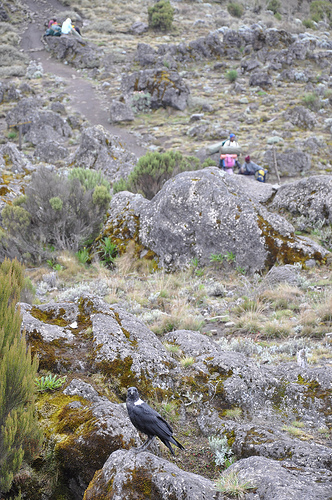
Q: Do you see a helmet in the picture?
A: No, there are no helmets.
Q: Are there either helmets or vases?
A: No, there are no helmets or vases.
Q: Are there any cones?
A: No, there are no cones.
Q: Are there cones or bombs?
A: No, there are no cones or bombs.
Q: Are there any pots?
A: No, there are no pots.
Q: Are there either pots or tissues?
A: No, there are no pots or tissues.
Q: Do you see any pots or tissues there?
A: No, there are no pots or tissues.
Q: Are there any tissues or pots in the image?
A: No, there are no pots or tissues.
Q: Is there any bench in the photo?
A: No, there are no benches.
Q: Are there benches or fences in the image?
A: No, there are no benches or fences.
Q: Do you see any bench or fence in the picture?
A: No, there are no benches or fences.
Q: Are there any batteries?
A: No, there are no batteries.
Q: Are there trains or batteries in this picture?
A: No, there are no batteries or trains.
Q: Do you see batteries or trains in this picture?
A: No, there are no batteries or trains.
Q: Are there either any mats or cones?
A: No, there are no cones or mats.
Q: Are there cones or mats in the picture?
A: No, there are no cones or mats.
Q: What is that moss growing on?
A: The moss is growing on the rocks.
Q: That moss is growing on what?
A: The moss is growing on the rocks.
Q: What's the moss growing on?
A: The moss is growing on the rocks.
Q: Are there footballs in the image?
A: No, there are no footballs.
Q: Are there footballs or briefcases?
A: No, there are no footballs or briefcases.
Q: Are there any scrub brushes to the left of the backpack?
A: Yes, there is a scrub brush to the left of the backpack.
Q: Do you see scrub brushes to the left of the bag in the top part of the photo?
A: Yes, there is a scrub brush to the left of the backpack.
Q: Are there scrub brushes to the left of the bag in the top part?
A: Yes, there is a scrub brush to the left of the backpack.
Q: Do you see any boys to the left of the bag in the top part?
A: No, there is a scrub brush to the left of the backpack.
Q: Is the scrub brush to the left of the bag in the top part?
A: Yes, the scrub brush is to the left of the backpack.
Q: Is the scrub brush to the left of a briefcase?
A: No, the scrub brush is to the left of the backpack.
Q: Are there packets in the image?
A: No, there are no packets.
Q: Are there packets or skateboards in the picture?
A: No, there are no packets or skateboards.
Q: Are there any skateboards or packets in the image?
A: No, there are no packets or skateboards.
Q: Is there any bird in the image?
A: Yes, there is a bird.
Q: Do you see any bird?
A: Yes, there is a bird.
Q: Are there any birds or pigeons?
A: Yes, there is a bird.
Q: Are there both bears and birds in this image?
A: No, there is a bird but no bears.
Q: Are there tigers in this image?
A: No, there are no tigers.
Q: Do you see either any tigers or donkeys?
A: No, there are no tigers or donkeys.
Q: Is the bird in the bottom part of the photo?
A: Yes, the bird is in the bottom of the image.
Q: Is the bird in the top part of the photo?
A: No, the bird is in the bottom of the image.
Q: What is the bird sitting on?
A: The bird is sitting on the rock.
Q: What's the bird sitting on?
A: The bird is sitting on the rock.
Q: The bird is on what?
A: The bird is on the rock.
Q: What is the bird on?
A: The bird is on the rock.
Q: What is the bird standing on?
A: The bird is standing on the rock.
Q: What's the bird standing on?
A: The bird is standing on the rock.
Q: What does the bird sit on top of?
A: The bird sits on top of the rock.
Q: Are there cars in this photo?
A: No, there are no cars.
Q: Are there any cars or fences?
A: No, there are no cars or fences.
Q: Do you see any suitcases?
A: No, there are no suitcases.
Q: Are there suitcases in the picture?
A: No, there are no suitcases.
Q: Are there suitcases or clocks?
A: No, there are no suitcases or clocks.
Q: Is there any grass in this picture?
A: Yes, there is grass.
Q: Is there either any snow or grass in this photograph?
A: Yes, there is grass.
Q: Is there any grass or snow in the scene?
A: Yes, there is grass.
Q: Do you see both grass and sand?
A: No, there is grass but no sand.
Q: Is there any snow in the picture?
A: No, there is no snow.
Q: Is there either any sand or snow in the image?
A: No, there are no snow or sand.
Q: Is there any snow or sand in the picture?
A: No, there are no snow or sand.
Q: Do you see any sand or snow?
A: No, there are no snow or sand.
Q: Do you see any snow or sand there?
A: No, there are no snow or sand.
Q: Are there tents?
A: No, there are no tents.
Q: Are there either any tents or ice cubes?
A: No, there are no tents or ice cubes.